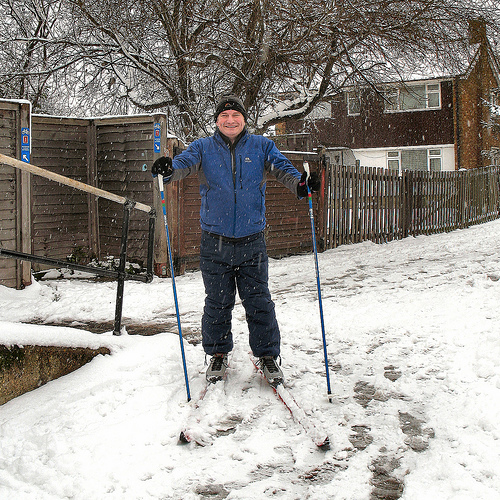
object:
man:
[150, 96, 319, 384]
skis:
[247, 355, 331, 447]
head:
[213, 94, 247, 140]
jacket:
[164, 134, 308, 239]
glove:
[150, 156, 173, 179]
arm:
[172, 139, 204, 181]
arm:
[264, 136, 302, 200]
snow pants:
[200, 232, 281, 358]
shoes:
[203, 353, 228, 384]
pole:
[302, 160, 334, 403]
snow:
[0, 218, 499, 498]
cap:
[212, 95, 251, 120]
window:
[383, 87, 398, 112]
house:
[271, 16, 500, 212]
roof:
[266, 38, 483, 100]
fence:
[325, 161, 500, 250]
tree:
[0, 1, 497, 137]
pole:
[155, 174, 192, 402]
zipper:
[231, 146, 237, 238]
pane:
[399, 86, 425, 109]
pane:
[427, 92, 440, 108]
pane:
[385, 95, 396, 112]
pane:
[400, 150, 427, 171]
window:
[385, 151, 401, 157]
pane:
[429, 157, 441, 175]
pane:
[387, 160, 398, 172]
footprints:
[366, 444, 406, 499]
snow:
[202, 398, 214, 422]